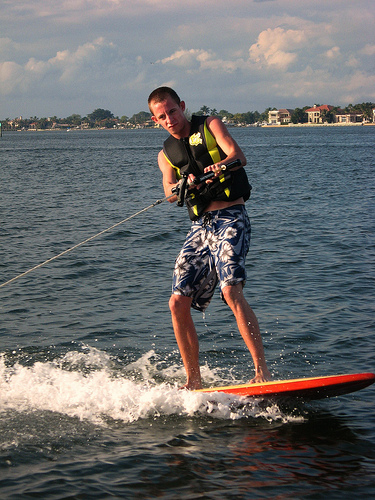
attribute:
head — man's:
[148, 86, 185, 134]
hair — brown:
[138, 80, 179, 111]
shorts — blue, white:
[169, 209, 256, 306]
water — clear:
[3, 132, 372, 370]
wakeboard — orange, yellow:
[153, 350, 372, 424]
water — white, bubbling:
[6, 131, 369, 499]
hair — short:
[141, 83, 189, 116]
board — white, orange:
[166, 363, 373, 404]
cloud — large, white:
[250, 25, 318, 76]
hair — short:
[146, 84, 181, 115]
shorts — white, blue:
[161, 200, 254, 315]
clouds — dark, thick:
[6, 15, 357, 78]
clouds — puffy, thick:
[150, 20, 367, 89]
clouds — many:
[220, 22, 344, 86]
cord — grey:
[3, 193, 176, 313]